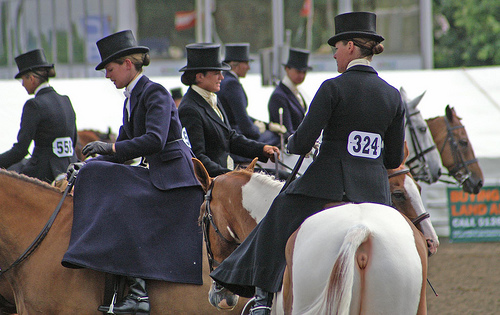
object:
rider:
[208, 11, 407, 314]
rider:
[60, 29, 206, 315]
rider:
[0, 49, 78, 186]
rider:
[177, 42, 280, 178]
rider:
[217, 43, 288, 142]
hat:
[328, 10, 383, 44]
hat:
[177, 38, 232, 73]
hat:
[221, 42, 255, 66]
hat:
[280, 46, 312, 70]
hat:
[10, 47, 55, 77]